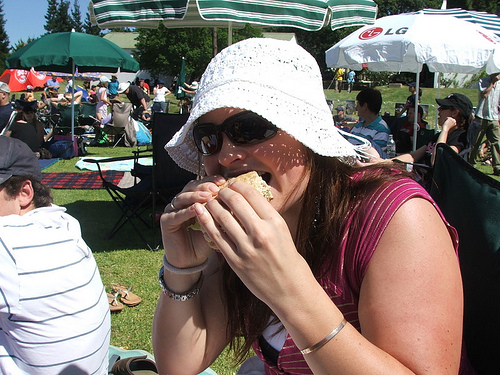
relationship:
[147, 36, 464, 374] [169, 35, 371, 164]
lady has hat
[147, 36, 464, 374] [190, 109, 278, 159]
lady on glasses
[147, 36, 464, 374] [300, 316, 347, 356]
lady on bracelet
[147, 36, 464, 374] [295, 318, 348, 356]
lady wearing bracelet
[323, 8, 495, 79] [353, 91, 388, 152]
umbrella over people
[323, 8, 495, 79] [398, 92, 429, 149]
umbrella over people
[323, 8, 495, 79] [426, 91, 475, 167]
umbrella over people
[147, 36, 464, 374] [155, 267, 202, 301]
lady wearing wrist watch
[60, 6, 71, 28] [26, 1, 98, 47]
leaves on tree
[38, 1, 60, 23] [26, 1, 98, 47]
branches on tree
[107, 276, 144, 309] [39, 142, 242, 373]
sandals on grass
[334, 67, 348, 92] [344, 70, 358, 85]
person in shirt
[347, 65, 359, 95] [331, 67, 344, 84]
person in shirt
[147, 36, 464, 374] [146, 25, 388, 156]
lady wearing hat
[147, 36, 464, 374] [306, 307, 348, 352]
lady wearing bracelet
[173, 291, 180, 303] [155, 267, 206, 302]
square on wrist watch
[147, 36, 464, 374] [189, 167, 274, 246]
lady eating sandwich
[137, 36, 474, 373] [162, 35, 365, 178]
lady in hat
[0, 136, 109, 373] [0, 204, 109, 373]
gentleman wears striped shirt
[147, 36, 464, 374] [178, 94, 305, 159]
lady wears sunglasses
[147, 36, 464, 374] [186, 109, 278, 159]
lady wears glasses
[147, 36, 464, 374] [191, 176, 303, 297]
lady has hand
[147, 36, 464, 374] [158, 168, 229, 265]
lady has hand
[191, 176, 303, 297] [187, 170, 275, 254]
hand holds sandwhich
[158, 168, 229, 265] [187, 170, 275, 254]
hand holds sandwhich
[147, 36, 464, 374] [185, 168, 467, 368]
lady wears shirt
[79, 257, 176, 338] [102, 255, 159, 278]
sandals are in grass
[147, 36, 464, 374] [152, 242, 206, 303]
lady wearing wristband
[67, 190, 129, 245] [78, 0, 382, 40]
shadow on tent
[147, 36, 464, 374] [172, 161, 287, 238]
lady eating sandwich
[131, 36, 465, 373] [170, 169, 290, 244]
woman eating eating woman eating